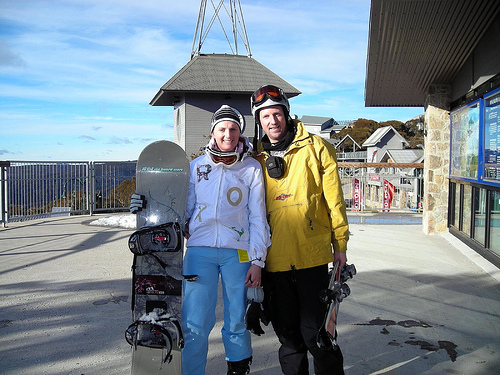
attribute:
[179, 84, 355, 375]
couple — posing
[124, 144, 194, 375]
snowboard — grey, black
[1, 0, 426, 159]
sky — light blue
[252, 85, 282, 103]
goggles — black framed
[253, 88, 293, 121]
helmet — white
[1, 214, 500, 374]
pavement — gray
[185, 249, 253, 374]
snowpants — light blue, blue, lighter blue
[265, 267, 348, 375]
pants — black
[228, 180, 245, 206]
o — gold, circle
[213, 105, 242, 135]
hat — black, white